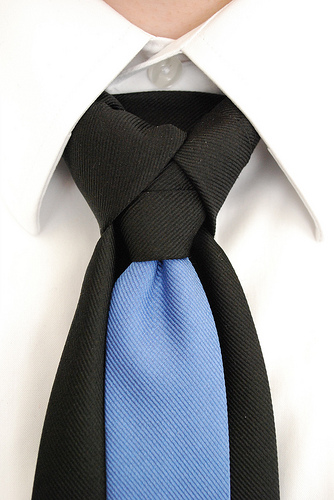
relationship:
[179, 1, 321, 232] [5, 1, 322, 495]
collar on shirt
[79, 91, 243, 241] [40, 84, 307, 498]
loop on necktie